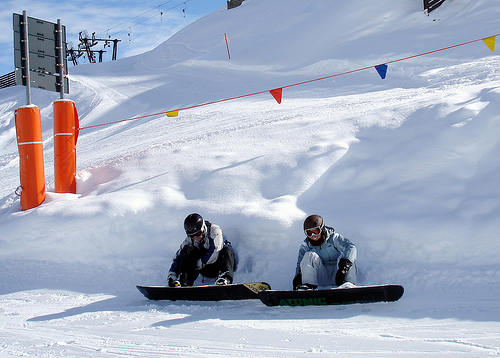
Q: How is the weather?
A: Clear.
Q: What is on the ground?
A: Snow.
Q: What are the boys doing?
A: Snowboarding.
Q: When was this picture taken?
A: Daytime.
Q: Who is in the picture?
A: Two boys.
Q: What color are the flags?
A: Yellow, orange and blue.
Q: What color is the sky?
A: Blue.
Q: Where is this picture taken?
A: A ski slope.